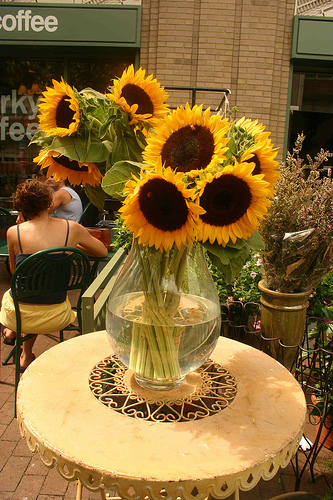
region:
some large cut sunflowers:
[35, 61, 279, 249]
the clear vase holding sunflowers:
[103, 230, 217, 386]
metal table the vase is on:
[15, 328, 300, 494]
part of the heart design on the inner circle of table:
[148, 399, 176, 418]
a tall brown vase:
[255, 278, 308, 365]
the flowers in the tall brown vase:
[257, 129, 328, 287]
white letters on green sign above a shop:
[0, 7, 55, 28]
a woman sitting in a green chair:
[0, 176, 106, 368]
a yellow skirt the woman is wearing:
[0, 285, 75, 328]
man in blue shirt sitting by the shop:
[46, 171, 91, 219]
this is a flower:
[25, 69, 284, 400]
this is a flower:
[110, 158, 204, 259]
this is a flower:
[190, 162, 276, 249]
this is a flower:
[140, 96, 228, 185]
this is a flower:
[225, 99, 281, 190]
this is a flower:
[26, 65, 104, 147]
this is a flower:
[108, 63, 172, 137]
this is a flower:
[11, 130, 108, 198]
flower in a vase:
[118, 169, 196, 255]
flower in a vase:
[180, 163, 268, 250]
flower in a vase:
[135, 98, 240, 198]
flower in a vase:
[244, 133, 284, 173]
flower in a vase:
[39, 67, 83, 143]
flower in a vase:
[111, 57, 177, 131]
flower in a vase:
[271, 166, 326, 224]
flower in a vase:
[267, 217, 282, 256]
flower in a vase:
[283, 232, 315, 261]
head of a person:
[0, 172, 64, 238]